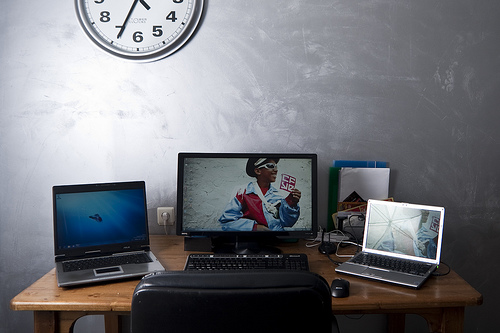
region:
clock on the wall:
[86, 1, 211, 64]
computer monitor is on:
[188, 133, 325, 234]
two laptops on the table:
[20, 175, 492, 297]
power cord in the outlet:
[155, 191, 184, 237]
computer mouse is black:
[326, 276, 361, 306]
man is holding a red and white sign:
[268, 175, 306, 200]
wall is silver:
[278, 26, 425, 98]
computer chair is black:
[99, 261, 355, 331]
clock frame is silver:
[74, 3, 240, 80]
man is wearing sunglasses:
[235, 157, 297, 178]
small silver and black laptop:
[40, 159, 170, 291]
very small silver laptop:
[329, 180, 453, 300]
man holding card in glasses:
[197, 152, 314, 226]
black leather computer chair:
[106, 256, 349, 331]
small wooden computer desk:
[8, 214, 497, 327]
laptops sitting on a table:
[8, 141, 488, 318]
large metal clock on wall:
[60, 1, 224, 68]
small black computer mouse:
[320, 268, 360, 309]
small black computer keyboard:
[169, 237, 321, 296]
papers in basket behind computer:
[304, 129, 421, 281]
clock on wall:
[66, 0, 211, 67]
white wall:
[54, 19, 495, 151]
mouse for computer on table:
[328, 268, 364, 298]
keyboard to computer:
[160, 250, 306, 271]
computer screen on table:
[178, 149, 327, 249]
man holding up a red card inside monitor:
[176, 155, 312, 227]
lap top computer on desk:
[335, 172, 437, 282]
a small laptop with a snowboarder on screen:
[46, 172, 158, 296]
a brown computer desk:
[23, 187, 491, 314]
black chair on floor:
[129, 278, 329, 328]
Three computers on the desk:
[57, 120, 455, 292]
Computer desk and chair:
[17, 102, 470, 328]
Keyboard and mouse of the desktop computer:
[173, 248, 359, 304]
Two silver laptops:
[28, 176, 451, 285]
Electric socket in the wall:
[148, 189, 194, 241]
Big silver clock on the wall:
[51, 0, 251, 60]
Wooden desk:
[23, 246, 484, 303]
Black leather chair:
[131, 267, 365, 319]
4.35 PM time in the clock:
[67, 0, 232, 67]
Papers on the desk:
[321, 141, 412, 243]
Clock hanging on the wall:
[92, 5, 213, 88]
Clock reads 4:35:
[51, 10, 221, 75]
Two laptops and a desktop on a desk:
[30, 165, 460, 290]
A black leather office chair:
[90, 257, 345, 319]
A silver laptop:
[355, 195, 436, 290]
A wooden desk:
[15, 260, 476, 327]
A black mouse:
[322, 272, 360, 300]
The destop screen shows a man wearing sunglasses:
[182, 132, 318, 247]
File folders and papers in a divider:
[320, 138, 390, 228]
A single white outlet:
[149, 192, 180, 234]